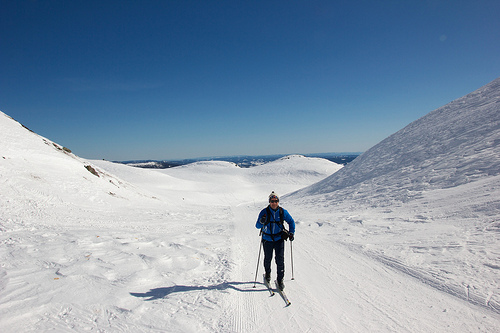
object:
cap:
[266, 188, 281, 204]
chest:
[264, 206, 284, 226]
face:
[268, 199, 282, 209]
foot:
[277, 277, 289, 290]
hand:
[287, 234, 299, 242]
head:
[266, 191, 281, 203]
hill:
[246, 152, 347, 183]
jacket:
[254, 206, 294, 244]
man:
[254, 192, 295, 292]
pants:
[260, 238, 287, 283]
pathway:
[237, 170, 499, 332]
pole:
[286, 240, 298, 284]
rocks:
[59, 144, 77, 154]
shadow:
[127, 279, 275, 303]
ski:
[263, 275, 279, 300]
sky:
[0, 1, 500, 159]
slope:
[330, 73, 499, 197]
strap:
[275, 206, 280, 233]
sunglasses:
[268, 196, 280, 204]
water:
[106, 150, 363, 159]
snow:
[1, 172, 500, 332]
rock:
[83, 161, 105, 178]